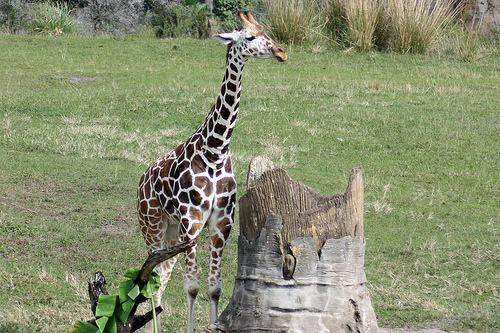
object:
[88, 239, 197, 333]
tree stump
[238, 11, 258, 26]
horn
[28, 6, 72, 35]
foliage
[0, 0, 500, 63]
shrubs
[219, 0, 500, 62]
brush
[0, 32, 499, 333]
ground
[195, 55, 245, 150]
neck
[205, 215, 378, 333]
bark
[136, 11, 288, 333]
giraffe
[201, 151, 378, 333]
stump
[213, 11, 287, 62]
head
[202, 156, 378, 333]
tree trunk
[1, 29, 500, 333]
grass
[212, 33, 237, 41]
ear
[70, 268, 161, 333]
plant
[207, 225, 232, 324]
leg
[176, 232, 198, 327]
leg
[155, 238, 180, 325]
leg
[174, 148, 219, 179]
spots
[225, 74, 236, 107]
spots